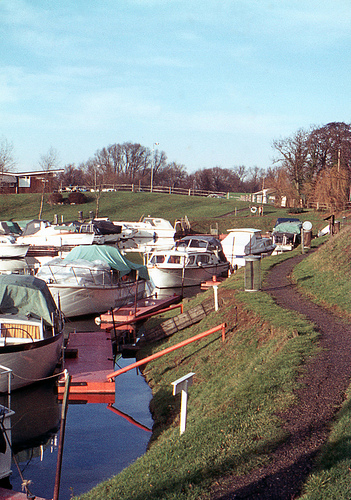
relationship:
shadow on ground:
[123, 398, 350, 496] [12, 176, 345, 487]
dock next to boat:
[55, 329, 115, 402] [1, 269, 70, 397]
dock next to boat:
[98, 292, 179, 319] [38, 245, 151, 319]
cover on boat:
[63, 247, 156, 289] [35, 242, 180, 317]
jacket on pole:
[257, 206, 262, 213] [257, 203, 262, 215]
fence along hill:
[58, 184, 348, 210] [0, 191, 325, 234]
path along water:
[201, 243, 331, 500] [12, 303, 160, 488]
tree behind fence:
[60, 120, 350, 214] [56, 182, 350, 211]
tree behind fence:
[90, 140, 166, 184] [56, 182, 350, 211]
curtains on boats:
[2, 320, 43, 342] [0, 275, 59, 395]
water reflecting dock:
[59, 401, 178, 498] [58, 332, 116, 408]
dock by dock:
[58, 331, 115, 405] [99, 286, 174, 331]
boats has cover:
[0, 275, 59, 395] [0, 274, 62, 330]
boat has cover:
[38, 245, 151, 319] [61, 245, 150, 281]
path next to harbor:
[235, 263, 343, 373] [0, 218, 299, 498]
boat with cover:
[38, 245, 151, 319] [63, 244, 155, 293]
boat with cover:
[145, 236, 227, 287] [178, 236, 219, 250]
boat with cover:
[269, 228, 295, 256] [273, 218, 300, 236]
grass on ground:
[2, 190, 347, 498] [4, 191, 350, 498]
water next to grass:
[0, 333, 154, 500] [107, 194, 227, 217]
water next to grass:
[0, 333, 154, 500] [146, 340, 290, 441]